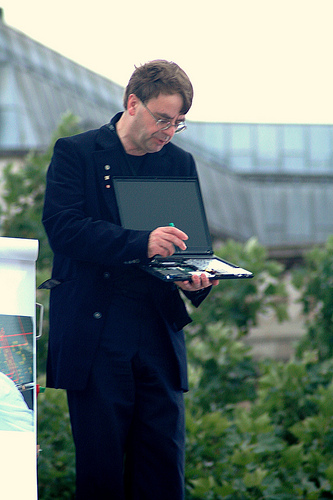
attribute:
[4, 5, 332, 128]
sky — light, gray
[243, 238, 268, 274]
leaves — green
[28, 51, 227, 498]
man — black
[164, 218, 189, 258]
tool — green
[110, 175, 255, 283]
laptop — open, black